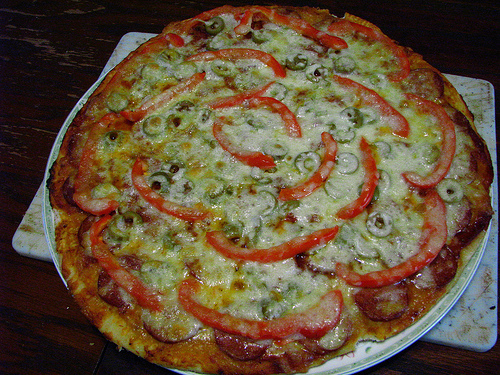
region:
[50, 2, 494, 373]
Delicious looking pizza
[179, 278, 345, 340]
Tomato slice in pizza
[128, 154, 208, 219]
Tomato slice in pizza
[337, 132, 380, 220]
Tomato slice in pizza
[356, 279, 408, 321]
Pepperoni slice in pizza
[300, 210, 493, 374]
Green and white plate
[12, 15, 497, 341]
Dirty white and brown cutting board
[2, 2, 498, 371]
Chipped brown wood surface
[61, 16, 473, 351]
Amazing melted cheese on pizza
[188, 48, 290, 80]
Tomato slice in pizza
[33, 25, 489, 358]
a yummy looking pizza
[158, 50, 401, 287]
it appears to have red peppers on it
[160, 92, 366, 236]
it also has lots of olives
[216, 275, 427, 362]
it also has some pepperoni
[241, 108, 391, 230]
it has lots of cheese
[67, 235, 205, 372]
the crust is golden brown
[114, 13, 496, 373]
the plate is white trimmed in blue & light green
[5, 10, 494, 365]
the pizza board is white with brown marks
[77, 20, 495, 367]
this pizza will make someone a tasty lunch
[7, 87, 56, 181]
the table it sets on is wooden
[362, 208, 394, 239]
black olive on a pizza covered in cheese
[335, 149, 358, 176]
black olive on a pizza covered in cheese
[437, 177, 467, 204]
black olive on a pizza covered in cheese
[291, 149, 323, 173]
black olive on a pizza covered in cheese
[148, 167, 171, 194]
black olive on a pizza covered in cheese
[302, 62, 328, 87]
black olive on a pizza covered in cheese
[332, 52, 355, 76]
black olive on a pizza covered in cheese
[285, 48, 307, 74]
black olive on a pizza covered in cheese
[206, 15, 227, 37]
black olive on a pizza covered in cheese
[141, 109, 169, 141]
black olive on a pizza covered in cheese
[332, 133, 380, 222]
red bell pepper on top of a pizza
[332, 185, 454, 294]
red bell pepper on top of a pizza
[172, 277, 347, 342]
red bell pepper on top of a pizza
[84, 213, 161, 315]
red bell pepper on top of a pizza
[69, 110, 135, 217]
red bell pepper on top of a pizza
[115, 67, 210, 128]
red bell pepper on top of a pizza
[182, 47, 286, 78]
red bell pepper on top of a pizza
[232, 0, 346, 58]
red bell pepper on top of a pizza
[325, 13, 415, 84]
red bell pepper on top of a pizza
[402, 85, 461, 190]
red bell pepper on top of a pizza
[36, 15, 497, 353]
a fancy pizza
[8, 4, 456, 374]
the way everything is arranged gives it a fancy look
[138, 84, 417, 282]
it has lots of red peppers on it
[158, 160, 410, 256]
it also has a lot of olives on it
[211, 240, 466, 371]
pepperoni is on the pizza as well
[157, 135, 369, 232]
the pizza is covered in yummy cheese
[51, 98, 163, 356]
the crust is nicely browned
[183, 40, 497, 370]
the serving plate is white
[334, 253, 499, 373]
the plate has light green & blue trim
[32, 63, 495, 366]
the pizza board it sets on appears to be marble